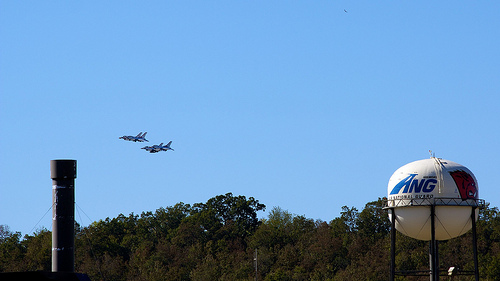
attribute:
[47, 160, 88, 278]
tower — large, metal, brown, black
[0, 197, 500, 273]
tree — green colored, green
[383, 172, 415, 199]
letter — blue, big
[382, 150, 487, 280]
water tower — metal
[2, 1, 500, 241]
sky — clear, blue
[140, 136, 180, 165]
plane — flying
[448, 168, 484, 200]
logo — red, animal